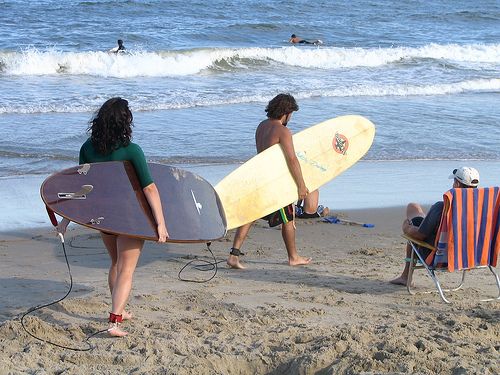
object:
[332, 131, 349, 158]
symbol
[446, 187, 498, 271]
towel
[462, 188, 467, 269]
stripe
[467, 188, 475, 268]
stripe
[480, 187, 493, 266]
stripe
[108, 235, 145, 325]
leg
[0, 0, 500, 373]
outside scene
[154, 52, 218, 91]
surf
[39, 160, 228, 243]
board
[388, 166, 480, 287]
man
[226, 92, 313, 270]
man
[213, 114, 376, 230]
surf board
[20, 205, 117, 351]
bracelet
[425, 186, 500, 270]
striped towel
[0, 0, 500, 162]
water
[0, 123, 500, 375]
beach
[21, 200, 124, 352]
leash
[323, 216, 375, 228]
shovel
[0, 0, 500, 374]
day time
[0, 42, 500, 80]
wave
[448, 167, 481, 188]
baseball cap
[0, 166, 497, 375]
sandy beach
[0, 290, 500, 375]
footprints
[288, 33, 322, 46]
man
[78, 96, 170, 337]
surfers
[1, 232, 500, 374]
sand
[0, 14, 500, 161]
ocean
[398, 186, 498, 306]
beach chair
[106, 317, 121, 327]
ankle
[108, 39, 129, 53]
surfer